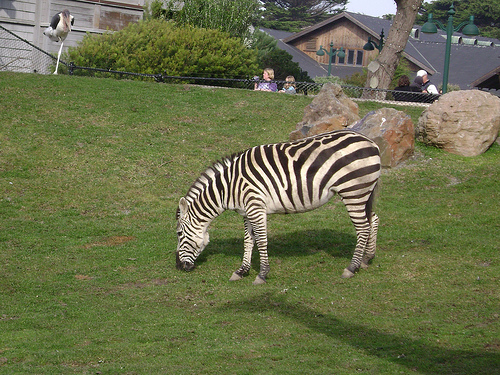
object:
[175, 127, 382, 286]
zebra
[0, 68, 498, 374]
grass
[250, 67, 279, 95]
woman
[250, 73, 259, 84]
camera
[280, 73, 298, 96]
girl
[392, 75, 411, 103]
person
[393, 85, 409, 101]
black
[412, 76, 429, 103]
person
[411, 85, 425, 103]
black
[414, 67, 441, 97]
man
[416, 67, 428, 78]
cap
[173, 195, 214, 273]
head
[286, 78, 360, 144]
boulder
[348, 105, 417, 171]
boulder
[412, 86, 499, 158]
boulder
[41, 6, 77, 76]
bird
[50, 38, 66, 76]
one leg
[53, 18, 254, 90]
bush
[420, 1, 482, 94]
lamp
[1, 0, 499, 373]
zoo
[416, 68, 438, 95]
person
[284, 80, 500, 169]
rocks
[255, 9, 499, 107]
building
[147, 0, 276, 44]
bush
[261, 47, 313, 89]
bush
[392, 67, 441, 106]
people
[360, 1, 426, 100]
tree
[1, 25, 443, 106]
enclosure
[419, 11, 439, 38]
light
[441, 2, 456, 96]
pole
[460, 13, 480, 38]
light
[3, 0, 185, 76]
building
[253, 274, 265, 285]
hoof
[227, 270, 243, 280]
hoof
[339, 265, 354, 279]
hoof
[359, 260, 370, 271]
hoof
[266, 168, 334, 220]
stomach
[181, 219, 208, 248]
jaw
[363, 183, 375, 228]
tail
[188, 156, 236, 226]
neck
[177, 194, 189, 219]
ear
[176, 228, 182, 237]
eye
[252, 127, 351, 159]
back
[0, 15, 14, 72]
edge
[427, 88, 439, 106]
edge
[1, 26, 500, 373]
enclosure